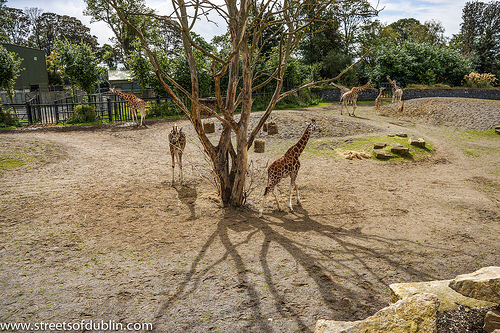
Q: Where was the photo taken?
A: It was taken at the zoo.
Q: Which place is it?
A: It is a zoo.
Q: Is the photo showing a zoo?
A: Yes, it is showing a zoo.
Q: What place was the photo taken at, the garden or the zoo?
A: It was taken at the zoo.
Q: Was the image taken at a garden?
A: No, the picture was taken in a zoo.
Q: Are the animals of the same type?
A: Yes, all the animals are giraffes.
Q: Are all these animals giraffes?
A: Yes, all the animals are giraffes.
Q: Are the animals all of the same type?
A: Yes, all the animals are giraffes.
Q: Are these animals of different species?
A: No, all the animals are giraffes.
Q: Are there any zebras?
A: No, there are no zebras.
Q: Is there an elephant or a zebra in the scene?
A: No, there are no zebras or elephants.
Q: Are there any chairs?
A: No, there are no chairs.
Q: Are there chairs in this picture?
A: No, there are no chairs.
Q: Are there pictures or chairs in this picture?
A: No, there are no chairs or pictures.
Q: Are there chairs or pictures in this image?
A: No, there are no chairs or pictures.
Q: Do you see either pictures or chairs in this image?
A: No, there are no chairs or pictures.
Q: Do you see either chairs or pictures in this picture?
A: No, there are no chairs or pictures.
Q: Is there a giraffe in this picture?
A: Yes, there is a giraffe.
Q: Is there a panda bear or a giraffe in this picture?
A: Yes, there is a giraffe.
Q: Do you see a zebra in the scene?
A: No, there are no zebras.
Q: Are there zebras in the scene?
A: No, there are no zebras.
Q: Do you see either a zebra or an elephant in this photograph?
A: No, there are no zebras or elephants.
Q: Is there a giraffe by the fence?
A: Yes, there is a giraffe by the fence.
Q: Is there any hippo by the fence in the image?
A: No, there is a giraffe by the fence.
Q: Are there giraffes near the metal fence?
A: Yes, there is a giraffe near the fence.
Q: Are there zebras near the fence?
A: No, there is a giraffe near the fence.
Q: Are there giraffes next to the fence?
A: Yes, there is a giraffe next to the fence.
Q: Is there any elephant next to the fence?
A: No, there is a giraffe next to the fence.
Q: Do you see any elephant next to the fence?
A: No, there is a giraffe next to the fence.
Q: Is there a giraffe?
A: Yes, there are giraffes.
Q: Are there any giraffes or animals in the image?
A: Yes, there are giraffes.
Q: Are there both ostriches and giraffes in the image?
A: No, there are giraffes but no ostriches.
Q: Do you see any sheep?
A: No, there are no sheep.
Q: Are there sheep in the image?
A: No, there are no sheep.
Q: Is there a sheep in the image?
A: No, there is no sheep.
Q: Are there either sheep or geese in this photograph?
A: No, there are no sheep or geese.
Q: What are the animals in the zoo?
A: The animals are giraffes.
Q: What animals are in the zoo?
A: The animals are giraffes.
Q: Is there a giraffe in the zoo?
A: Yes, there are giraffes in the zoo.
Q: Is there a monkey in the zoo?
A: No, there are giraffes in the zoo.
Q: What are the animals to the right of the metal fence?
A: The animals are giraffes.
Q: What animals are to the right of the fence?
A: The animals are giraffes.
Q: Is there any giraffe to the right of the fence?
A: Yes, there are giraffes to the right of the fence.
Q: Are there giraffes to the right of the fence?
A: Yes, there are giraffes to the right of the fence.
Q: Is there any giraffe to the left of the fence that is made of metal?
A: No, the giraffes are to the right of the fence.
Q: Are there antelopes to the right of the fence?
A: No, there are giraffes to the right of the fence.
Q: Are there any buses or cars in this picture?
A: No, there are no cars or buses.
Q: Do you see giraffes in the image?
A: Yes, there is a giraffe.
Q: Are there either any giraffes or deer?
A: Yes, there is a giraffe.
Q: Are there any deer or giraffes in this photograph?
A: Yes, there is a giraffe.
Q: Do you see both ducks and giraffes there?
A: No, there is a giraffe but no ducks.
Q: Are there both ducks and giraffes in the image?
A: No, there is a giraffe but no ducks.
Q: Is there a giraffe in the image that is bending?
A: Yes, there is a giraffe that is bending.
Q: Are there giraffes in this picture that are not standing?
A: Yes, there is a giraffe that is bending.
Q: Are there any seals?
A: No, there are no seals.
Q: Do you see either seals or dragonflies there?
A: No, there are no seals or dragonflies.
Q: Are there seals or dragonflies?
A: No, there are no seals or dragonflies.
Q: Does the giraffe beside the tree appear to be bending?
A: Yes, the giraffe is bending.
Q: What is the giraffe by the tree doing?
A: The giraffe is bending.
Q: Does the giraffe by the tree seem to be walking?
A: No, the giraffe is bending.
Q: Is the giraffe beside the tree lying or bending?
A: The giraffe is bending.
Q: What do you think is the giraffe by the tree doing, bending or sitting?
A: The giraffe is bending.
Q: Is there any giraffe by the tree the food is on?
A: Yes, there is a giraffe by the tree.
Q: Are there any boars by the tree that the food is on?
A: No, there is a giraffe by the tree.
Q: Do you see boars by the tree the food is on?
A: No, there is a giraffe by the tree.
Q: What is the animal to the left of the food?
A: The animal is a giraffe.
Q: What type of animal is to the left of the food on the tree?
A: The animal is a giraffe.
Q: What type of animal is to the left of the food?
A: The animal is a giraffe.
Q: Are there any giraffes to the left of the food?
A: Yes, there is a giraffe to the left of the food.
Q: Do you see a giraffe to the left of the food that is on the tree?
A: Yes, there is a giraffe to the left of the food.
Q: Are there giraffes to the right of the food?
A: No, the giraffe is to the left of the food.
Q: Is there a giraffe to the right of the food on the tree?
A: No, the giraffe is to the left of the food.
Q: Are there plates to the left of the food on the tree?
A: No, there is a giraffe to the left of the food.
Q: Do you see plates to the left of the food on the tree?
A: No, there is a giraffe to the left of the food.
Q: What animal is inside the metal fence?
A: The animal is a giraffe.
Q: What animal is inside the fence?
A: The animal is a giraffe.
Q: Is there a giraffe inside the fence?
A: Yes, there is a giraffe inside the fence.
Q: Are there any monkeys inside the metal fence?
A: No, there is a giraffe inside the fence.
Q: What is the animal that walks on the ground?
A: The animal is a giraffe.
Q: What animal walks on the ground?
A: The animal is a giraffe.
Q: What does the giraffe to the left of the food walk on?
A: The giraffe walks on the ground.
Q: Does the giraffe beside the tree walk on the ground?
A: Yes, the giraffe walks on the ground.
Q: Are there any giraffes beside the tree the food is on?
A: Yes, there is a giraffe beside the tree.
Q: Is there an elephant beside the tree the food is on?
A: No, there is a giraffe beside the tree.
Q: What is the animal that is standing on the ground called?
A: The animal is a giraffe.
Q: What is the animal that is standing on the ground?
A: The animal is a giraffe.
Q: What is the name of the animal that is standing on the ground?
A: The animal is a giraffe.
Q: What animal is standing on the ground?
A: The animal is a giraffe.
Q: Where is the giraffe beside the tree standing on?
A: The giraffe is standing on the ground.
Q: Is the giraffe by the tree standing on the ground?
A: Yes, the giraffe is standing on the ground.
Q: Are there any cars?
A: No, there are no cars.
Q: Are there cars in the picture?
A: No, there are no cars.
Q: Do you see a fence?
A: Yes, there is a fence.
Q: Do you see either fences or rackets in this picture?
A: Yes, there is a fence.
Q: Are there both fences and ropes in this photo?
A: No, there is a fence but no ropes.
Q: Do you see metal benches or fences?
A: Yes, there is a metal fence.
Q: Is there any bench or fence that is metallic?
A: Yes, the fence is metallic.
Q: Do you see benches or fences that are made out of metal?
A: Yes, the fence is made of metal.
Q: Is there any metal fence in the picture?
A: Yes, there is a metal fence.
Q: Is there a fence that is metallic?
A: Yes, there is a fence that is metallic.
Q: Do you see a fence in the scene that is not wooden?
A: Yes, there is a metallic fence.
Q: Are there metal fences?
A: Yes, there is a fence that is made of metal.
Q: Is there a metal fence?
A: Yes, there is a fence that is made of metal.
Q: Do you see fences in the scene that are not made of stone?
A: Yes, there is a fence that is made of metal.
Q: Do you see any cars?
A: No, there are no cars.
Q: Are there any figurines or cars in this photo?
A: No, there are no cars or figurines.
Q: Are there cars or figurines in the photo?
A: No, there are no cars or figurines.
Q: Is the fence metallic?
A: Yes, the fence is metallic.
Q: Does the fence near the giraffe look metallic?
A: Yes, the fence is metallic.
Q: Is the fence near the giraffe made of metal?
A: Yes, the fence is made of metal.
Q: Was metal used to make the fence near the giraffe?
A: Yes, the fence is made of metal.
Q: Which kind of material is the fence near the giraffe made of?
A: The fence is made of metal.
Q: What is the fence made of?
A: The fence is made of metal.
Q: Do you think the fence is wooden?
A: No, the fence is metallic.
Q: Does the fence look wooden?
A: No, the fence is metallic.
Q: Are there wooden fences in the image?
A: No, there is a fence but it is metallic.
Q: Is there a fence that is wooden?
A: No, there is a fence but it is metallic.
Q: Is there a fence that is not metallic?
A: No, there is a fence but it is metallic.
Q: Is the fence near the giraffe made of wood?
A: No, the fence is made of metal.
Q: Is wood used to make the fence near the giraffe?
A: No, the fence is made of metal.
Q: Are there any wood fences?
A: No, there is a fence but it is made of metal.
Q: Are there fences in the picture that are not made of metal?
A: No, there is a fence but it is made of metal.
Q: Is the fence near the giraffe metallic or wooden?
A: The fence is metallic.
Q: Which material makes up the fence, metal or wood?
A: The fence is made of metal.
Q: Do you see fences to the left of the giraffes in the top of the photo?
A: Yes, there is a fence to the left of the giraffes.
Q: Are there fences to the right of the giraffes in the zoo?
A: No, the fence is to the left of the giraffes.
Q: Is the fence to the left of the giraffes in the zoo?
A: Yes, the fence is to the left of the giraffes.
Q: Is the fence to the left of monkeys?
A: No, the fence is to the left of the giraffes.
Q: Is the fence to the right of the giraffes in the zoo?
A: No, the fence is to the left of the giraffes.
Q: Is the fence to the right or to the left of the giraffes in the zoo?
A: The fence is to the left of the giraffes.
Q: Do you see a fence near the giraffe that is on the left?
A: Yes, there is a fence near the giraffe.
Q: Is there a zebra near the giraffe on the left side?
A: No, there is a fence near the giraffe.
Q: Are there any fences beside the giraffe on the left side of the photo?
A: Yes, there is a fence beside the giraffe.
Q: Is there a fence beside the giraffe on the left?
A: Yes, there is a fence beside the giraffe.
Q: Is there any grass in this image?
A: Yes, there is grass.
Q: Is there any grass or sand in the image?
A: Yes, there is grass.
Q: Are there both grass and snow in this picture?
A: No, there is grass but no snow.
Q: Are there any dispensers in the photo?
A: No, there are no dispensers.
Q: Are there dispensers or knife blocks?
A: No, there are no dispensers or knife blocks.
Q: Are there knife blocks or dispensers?
A: No, there are no dispensers or knife blocks.